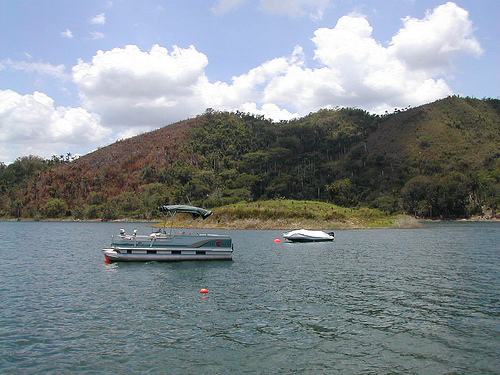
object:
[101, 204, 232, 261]
boat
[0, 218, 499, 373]
water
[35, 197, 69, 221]
trees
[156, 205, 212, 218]
canopy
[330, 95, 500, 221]
hills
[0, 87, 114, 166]
clouds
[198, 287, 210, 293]
buoy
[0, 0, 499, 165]
sky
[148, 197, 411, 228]
grass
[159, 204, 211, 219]
canvas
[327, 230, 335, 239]
motor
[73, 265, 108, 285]
edge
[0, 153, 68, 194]
vegetation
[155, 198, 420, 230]
island